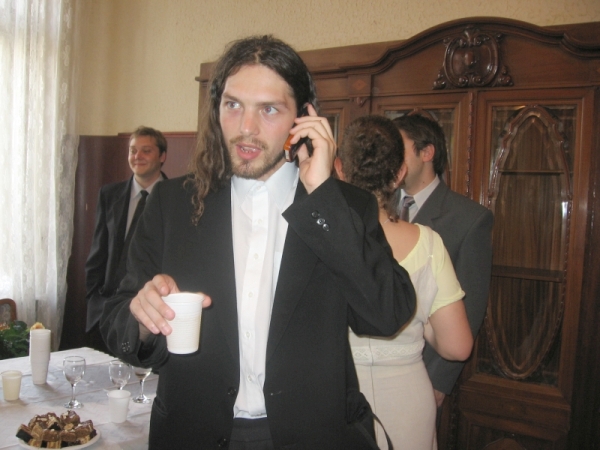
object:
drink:
[107, 389, 131, 424]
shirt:
[231, 162, 303, 422]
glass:
[63, 356, 88, 409]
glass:
[109, 361, 132, 390]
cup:
[1, 370, 23, 401]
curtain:
[0, 0, 83, 353]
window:
[0, 0, 63, 304]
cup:
[160, 292, 201, 355]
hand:
[128, 274, 211, 336]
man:
[98, 34, 417, 450]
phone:
[284, 107, 310, 162]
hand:
[288, 103, 336, 195]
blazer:
[100, 171, 419, 450]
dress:
[347, 220, 466, 450]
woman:
[331, 116, 472, 450]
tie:
[113, 190, 149, 288]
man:
[84, 124, 169, 331]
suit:
[84, 171, 172, 335]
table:
[0, 346, 159, 450]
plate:
[16, 411, 101, 450]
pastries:
[15, 409, 98, 449]